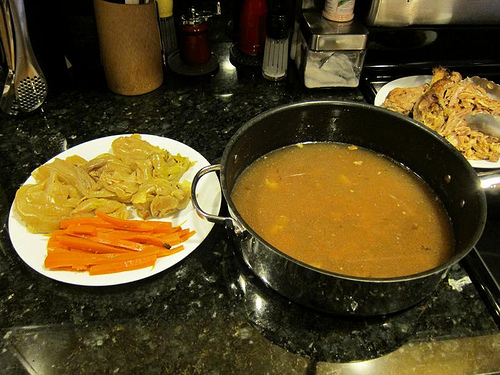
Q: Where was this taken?
A: A kitchen.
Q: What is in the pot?
A: Soupy broth.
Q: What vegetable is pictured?
A: Orange carrots.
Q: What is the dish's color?
A: White.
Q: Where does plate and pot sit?
A: Granite countertop.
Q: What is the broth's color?
A: Brown.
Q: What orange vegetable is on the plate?
A: Carrots.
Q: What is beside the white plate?
A: A black pot.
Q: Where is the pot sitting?
A: Countertop.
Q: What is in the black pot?
A: Broth.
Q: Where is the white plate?
A: Beside the pot.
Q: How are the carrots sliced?
A: Length wise.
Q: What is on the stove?
A: White plate.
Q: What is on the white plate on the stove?
A: Chicken.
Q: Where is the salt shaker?
A: Back of the counter.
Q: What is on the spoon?
A: Little holes.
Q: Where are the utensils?
A: Behind the food.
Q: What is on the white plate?
A: Cooked carrots and cabbage.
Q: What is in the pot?
A: Chicken stock.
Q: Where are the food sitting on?
A: A black countertop.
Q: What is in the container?
A: Kitchen utensils.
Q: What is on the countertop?
A: Food.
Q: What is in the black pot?
A: Chicken soup.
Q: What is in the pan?
A: Soup.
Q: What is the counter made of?
A: Black marble.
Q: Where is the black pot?
A: On the countertop.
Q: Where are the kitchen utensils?
A: Top left.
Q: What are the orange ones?
A: Carrots.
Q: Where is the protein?
A: On a white plate.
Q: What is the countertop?
A: Granite.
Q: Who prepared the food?
A: The cook.